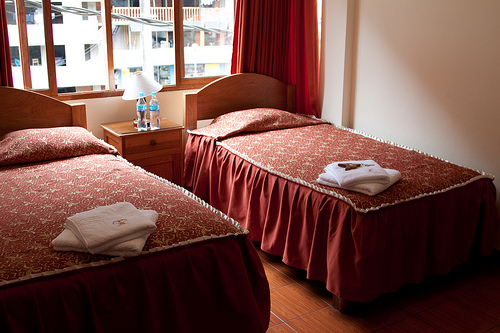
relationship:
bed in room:
[182, 75, 498, 311] [2, 5, 499, 330]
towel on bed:
[323, 159, 391, 187] [182, 75, 498, 311]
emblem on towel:
[333, 158, 368, 172] [323, 153, 392, 186]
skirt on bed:
[186, 134, 352, 236] [182, 75, 498, 311]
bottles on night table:
[137, 97, 163, 131] [99, 114, 186, 190]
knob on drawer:
[150, 139, 159, 149] [123, 135, 187, 157]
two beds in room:
[0, 78, 493, 325] [2, 5, 499, 330]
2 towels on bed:
[52, 203, 163, 254] [0, 90, 256, 287]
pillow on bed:
[218, 109, 315, 133] [182, 75, 498, 311]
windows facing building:
[6, 6, 239, 87] [121, 8, 172, 89]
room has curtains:
[2, 5, 499, 330] [233, 2, 319, 113]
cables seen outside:
[116, 14, 171, 33] [116, 9, 231, 87]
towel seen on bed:
[323, 159, 391, 187] [182, 75, 498, 311]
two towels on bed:
[52, 203, 163, 254] [0, 90, 256, 287]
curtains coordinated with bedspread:
[233, 2, 319, 113] [191, 110, 500, 262]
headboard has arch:
[187, 73, 309, 116] [197, 74, 292, 93]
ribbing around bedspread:
[346, 175, 490, 218] [191, 110, 500, 262]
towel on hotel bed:
[323, 159, 391, 187] [182, 75, 498, 311]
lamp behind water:
[123, 70, 163, 131] [137, 97, 163, 131]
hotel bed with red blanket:
[182, 75, 498, 311] [191, 110, 500, 262]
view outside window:
[6, 1, 230, 92] [109, 2, 184, 90]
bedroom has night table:
[2, 5, 499, 330] [99, 114, 186, 190]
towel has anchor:
[323, 153, 392, 186] [342, 159, 364, 174]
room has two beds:
[2, 5, 499, 330] [0, 78, 493, 325]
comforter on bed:
[191, 110, 500, 262] [182, 75, 498, 311]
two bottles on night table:
[137, 97, 163, 131] [106, 124, 186, 171]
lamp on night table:
[123, 70, 163, 131] [99, 114, 186, 190]